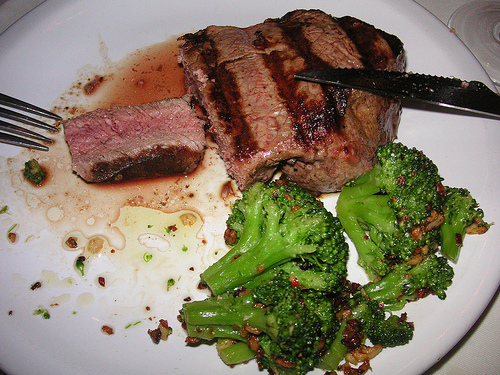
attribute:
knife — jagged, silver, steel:
[293, 68, 498, 118]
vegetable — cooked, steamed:
[185, 272, 315, 345]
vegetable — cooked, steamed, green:
[202, 183, 341, 295]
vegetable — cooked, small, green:
[440, 182, 488, 263]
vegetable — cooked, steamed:
[335, 142, 448, 277]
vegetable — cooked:
[364, 254, 454, 310]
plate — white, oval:
[1, 2, 499, 373]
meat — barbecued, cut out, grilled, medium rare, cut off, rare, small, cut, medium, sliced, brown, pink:
[63, 96, 208, 182]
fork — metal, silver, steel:
[0, 91, 60, 150]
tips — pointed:
[32, 106, 62, 151]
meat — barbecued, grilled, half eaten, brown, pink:
[180, 8, 407, 193]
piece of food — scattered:
[76, 259, 84, 274]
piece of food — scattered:
[99, 276, 105, 285]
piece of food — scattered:
[25, 162, 44, 184]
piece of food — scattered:
[66, 236, 76, 248]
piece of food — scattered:
[103, 326, 112, 334]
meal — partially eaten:
[63, 9, 489, 374]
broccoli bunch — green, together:
[184, 142, 490, 374]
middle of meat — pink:
[65, 106, 201, 154]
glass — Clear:
[447, 1, 499, 88]